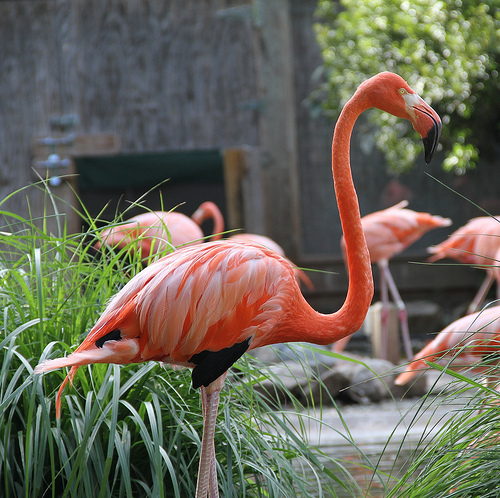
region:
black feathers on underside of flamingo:
[183, 335, 253, 394]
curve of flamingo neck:
[301, 295, 380, 346]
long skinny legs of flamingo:
[191, 373, 227, 496]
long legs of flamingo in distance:
[336, 207, 449, 370]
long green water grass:
[2, 215, 37, 497]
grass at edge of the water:
[285, 439, 499, 495]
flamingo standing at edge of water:
[46, 63, 445, 497]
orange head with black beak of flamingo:
[363, 70, 447, 162]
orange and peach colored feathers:
[169, 257, 256, 317]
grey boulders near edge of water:
[256, 352, 403, 422]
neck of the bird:
[300, 154, 408, 263]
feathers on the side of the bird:
[157, 270, 279, 350]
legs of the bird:
[161, 382, 263, 496]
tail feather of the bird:
[35, 322, 132, 429]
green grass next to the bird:
[71, 391, 186, 473]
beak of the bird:
[409, 103, 464, 163]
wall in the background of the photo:
[89, 20, 231, 118]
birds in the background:
[366, 189, 488, 286]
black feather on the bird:
[185, 334, 257, 397]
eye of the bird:
[388, 78, 424, 106]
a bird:
[45, 72, 447, 493]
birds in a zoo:
[40, 64, 497, 495]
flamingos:
[22, 64, 497, 495]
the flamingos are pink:
[25, 67, 497, 495]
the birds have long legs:
[56, 64, 488, 489]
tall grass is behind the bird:
[1, 175, 481, 496]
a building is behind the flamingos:
[0, 12, 495, 307]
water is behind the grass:
[223, 391, 497, 496]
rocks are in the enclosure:
[235, 332, 442, 409]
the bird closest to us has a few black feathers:
[26, 54, 466, 495]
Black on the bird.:
[177, 338, 252, 401]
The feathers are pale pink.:
[132, 264, 204, 307]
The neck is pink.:
[273, 117, 401, 340]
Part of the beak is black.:
[393, 120, 461, 160]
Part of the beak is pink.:
[381, 96, 466, 135]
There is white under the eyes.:
[387, 83, 436, 125]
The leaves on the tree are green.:
[372, 15, 492, 68]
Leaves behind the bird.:
[1, 405, 118, 480]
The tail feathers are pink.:
[23, 367, 101, 428]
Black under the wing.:
[83, 328, 140, 364]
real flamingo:
[56, 67, 483, 477]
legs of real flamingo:
[160, 360, 307, 491]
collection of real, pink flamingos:
[60, 124, 469, 489]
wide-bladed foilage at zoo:
[0, 170, 340, 489]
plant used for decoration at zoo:
[360, 292, 488, 496]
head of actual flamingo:
[357, 50, 459, 177]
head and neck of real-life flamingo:
[290, 40, 480, 354]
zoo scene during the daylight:
[28, 42, 465, 474]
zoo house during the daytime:
[6, 14, 478, 325]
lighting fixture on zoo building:
[14, 141, 91, 207]